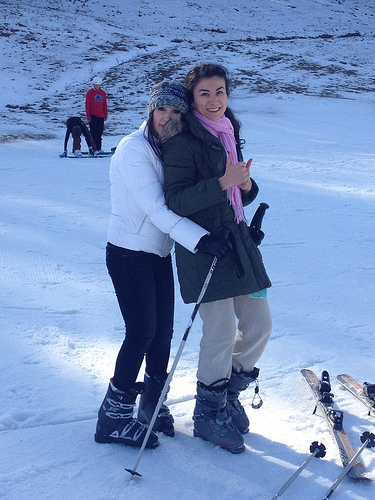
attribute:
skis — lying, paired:
[130, 444, 159, 465]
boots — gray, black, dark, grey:
[110, 396, 157, 438]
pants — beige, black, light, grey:
[197, 309, 263, 367]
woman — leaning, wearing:
[105, 58, 175, 247]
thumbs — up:
[223, 153, 253, 169]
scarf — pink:
[203, 118, 243, 152]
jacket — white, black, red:
[93, 167, 153, 231]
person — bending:
[55, 125, 84, 154]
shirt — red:
[90, 106, 103, 116]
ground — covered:
[242, 10, 293, 43]